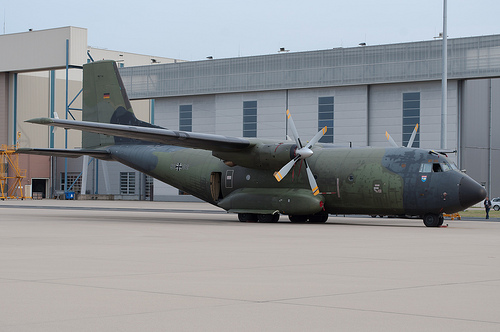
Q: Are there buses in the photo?
A: No, there are no buses.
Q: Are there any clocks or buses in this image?
A: No, there are no buses or clocks.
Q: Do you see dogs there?
A: No, there are no dogs.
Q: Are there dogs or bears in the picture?
A: No, there are no dogs or bears.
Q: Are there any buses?
A: No, there are no buses.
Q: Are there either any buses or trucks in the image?
A: No, there are no buses or trucks.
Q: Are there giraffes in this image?
A: No, there are no giraffes.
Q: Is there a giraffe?
A: No, there are no giraffes.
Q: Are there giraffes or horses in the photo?
A: No, there are no giraffes or horses.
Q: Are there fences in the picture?
A: Yes, there is a fence.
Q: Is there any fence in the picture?
A: Yes, there is a fence.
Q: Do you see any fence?
A: Yes, there is a fence.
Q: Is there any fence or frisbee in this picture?
A: Yes, there is a fence.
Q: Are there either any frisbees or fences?
A: Yes, there is a fence.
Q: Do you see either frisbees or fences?
A: Yes, there is a fence.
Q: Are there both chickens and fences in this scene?
A: No, there is a fence but no chickens.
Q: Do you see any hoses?
A: No, there are no hoses.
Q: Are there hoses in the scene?
A: No, there are no hoses.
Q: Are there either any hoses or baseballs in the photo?
A: No, there are no hoses or baseballs.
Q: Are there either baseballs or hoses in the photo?
A: No, there are no hoses or baseballs.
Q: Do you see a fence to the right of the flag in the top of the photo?
A: Yes, there is a fence to the right of the flag.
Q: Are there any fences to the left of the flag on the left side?
A: No, the fence is to the right of the flag.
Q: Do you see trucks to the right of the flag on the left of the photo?
A: No, there is a fence to the right of the flag.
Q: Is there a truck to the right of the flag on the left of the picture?
A: No, there is a fence to the right of the flag.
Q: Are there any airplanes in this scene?
A: Yes, there is an airplane.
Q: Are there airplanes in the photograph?
A: Yes, there is an airplane.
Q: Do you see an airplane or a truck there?
A: Yes, there is an airplane.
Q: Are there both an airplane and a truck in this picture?
A: No, there is an airplane but no trucks.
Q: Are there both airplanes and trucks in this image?
A: No, there is an airplane but no trucks.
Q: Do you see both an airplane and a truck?
A: No, there is an airplane but no trucks.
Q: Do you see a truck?
A: No, there are no trucks.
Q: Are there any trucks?
A: No, there are no trucks.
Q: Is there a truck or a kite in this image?
A: No, there are no trucks or kites.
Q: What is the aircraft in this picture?
A: The aircraft is an airplane.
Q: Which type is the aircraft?
A: The aircraft is an airplane.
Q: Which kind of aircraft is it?
A: The aircraft is an airplane.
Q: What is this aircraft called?
A: That is an airplane.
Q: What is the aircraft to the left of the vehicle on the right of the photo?
A: The aircraft is an airplane.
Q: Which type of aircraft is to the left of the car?
A: The aircraft is an airplane.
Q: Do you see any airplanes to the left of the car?
A: Yes, there is an airplane to the left of the car.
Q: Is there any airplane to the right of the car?
A: No, the airplane is to the left of the car.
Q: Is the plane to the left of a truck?
A: No, the plane is to the left of the car.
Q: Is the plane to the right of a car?
A: No, the plane is to the left of a car.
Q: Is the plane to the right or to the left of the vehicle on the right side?
A: The plane is to the left of the car.